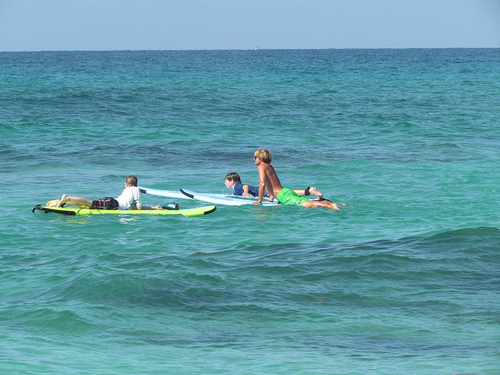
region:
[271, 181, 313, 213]
neon green swimtrunks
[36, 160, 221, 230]
a boy on a yellow surfboard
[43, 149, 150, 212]
a boy in a white shirt and black swim trunks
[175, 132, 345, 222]
a man on a black and white surf board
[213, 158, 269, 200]
a boy with brown hair and a blue shirt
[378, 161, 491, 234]
blue green ocean water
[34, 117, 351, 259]
three people on surf boards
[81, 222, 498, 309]
shallow ocean wave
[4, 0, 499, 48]
clear blue sky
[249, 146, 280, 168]
blond haired man with black sunglasses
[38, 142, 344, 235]
three boys on surfboards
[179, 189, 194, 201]
black tip on surfboard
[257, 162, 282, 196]
bare torso of boy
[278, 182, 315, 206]
green shorts on boy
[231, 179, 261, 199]
blue short sleeved tee shirt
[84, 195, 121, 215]
plaid shorts on boy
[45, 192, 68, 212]
bare feet on boy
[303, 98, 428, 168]
choppy surface of water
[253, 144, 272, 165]
blonde hair of boy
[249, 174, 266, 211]
arm holding up boy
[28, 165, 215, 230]
surfer lying on green board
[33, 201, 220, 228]
surfboard is light green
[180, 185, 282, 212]
surfboard is light blue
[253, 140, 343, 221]
surfer wearing green shorts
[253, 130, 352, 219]
surfer is sitting up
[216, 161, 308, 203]
child in blue shirt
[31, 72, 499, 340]
water is clear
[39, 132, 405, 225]
group of surfers on the water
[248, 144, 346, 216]
man has blonde hair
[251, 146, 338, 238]
man is on board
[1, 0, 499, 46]
a blue sky over the ocean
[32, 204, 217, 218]
a green surfboard on the water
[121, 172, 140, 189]
the head of a man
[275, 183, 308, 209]
a pair of green shorts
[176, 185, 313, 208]
a pale blue surfboard on the water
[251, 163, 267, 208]
the arm of a man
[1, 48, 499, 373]
a stretch of bright blue ocean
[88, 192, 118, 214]
a pair of black shorts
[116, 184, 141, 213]
a white shirt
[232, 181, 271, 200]
a blue shirt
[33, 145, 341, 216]
three surfers waiting for a wave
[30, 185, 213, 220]
the boy has a yellow surfboard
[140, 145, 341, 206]
two surfers on their boards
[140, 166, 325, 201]
the boy is tethered to his board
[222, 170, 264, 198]
the boy is wearing a blue shirt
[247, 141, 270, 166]
the boy has blonde hair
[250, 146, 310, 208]
the boy is wearing a green bathing suit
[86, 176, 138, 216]
the boy is wearing black trunks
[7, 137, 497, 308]
the boys are in between swells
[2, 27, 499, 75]
the deep water is dark blue